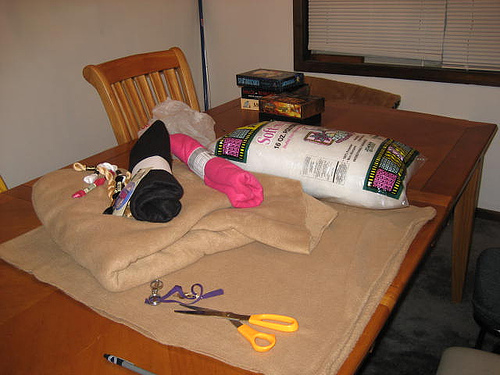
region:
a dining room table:
[7, 22, 494, 350]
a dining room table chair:
[65, 20, 257, 167]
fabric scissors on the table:
[122, 260, 276, 362]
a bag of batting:
[201, 77, 474, 241]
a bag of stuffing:
[215, 99, 492, 262]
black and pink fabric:
[102, 102, 307, 249]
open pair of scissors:
[152, 265, 287, 372]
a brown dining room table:
[314, 66, 496, 221]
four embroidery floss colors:
[32, 134, 176, 223]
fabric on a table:
[58, 72, 460, 371]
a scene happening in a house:
[5, 3, 483, 373]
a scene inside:
[12, 10, 492, 342]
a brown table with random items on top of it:
[23, 51, 498, 373]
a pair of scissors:
[164, 288, 314, 357]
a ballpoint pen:
[92, 340, 167, 374]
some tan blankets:
[12, 155, 396, 372]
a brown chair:
[77, 37, 206, 154]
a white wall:
[0, 0, 229, 191]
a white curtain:
[293, 2, 498, 74]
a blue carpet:
[327, 190, 495, 367]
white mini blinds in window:
[301, 9, 499, 76]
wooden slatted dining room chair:
[79, 54, 219, 151]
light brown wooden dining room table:
[8, 295, 80, 372]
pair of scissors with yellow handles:
[173, 301, 305, 358]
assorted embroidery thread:
[61, 144, 130, 212]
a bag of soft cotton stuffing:
[216, 114, 435, 212]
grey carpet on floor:
[390, 296, 434, 373]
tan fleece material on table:
[254, 258, 396, 301]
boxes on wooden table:
[224, 65, 345, 126]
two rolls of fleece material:
[128, 119, 270, 237]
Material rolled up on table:
[120, 122, 291, 240]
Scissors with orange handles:
[178, 301, 335, 372]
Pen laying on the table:
[94, 350, 154, 374]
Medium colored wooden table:
[29, 305, 65, 360]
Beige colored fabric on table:
[246, 261, 400, 357]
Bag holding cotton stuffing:
[222, 117, 434, 205]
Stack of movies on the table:
[230, 57, 331, 133]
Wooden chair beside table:
[73, 55, 222, 125]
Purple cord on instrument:
[140, 272, 268, 302]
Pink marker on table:
[71, 174, 113, 209]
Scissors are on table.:
[0, 64, 494, 374]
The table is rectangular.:
[1, 70, 498, 373]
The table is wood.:
[0, 68, 499, 373]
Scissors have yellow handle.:
[172, 293, 302, 361]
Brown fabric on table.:
[1, 58, 495, 373]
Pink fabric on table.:
[4, 67, 488, 372]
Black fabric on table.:
[6, 55, 496, 370]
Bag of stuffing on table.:
[3, 54, 499, 359]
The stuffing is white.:
[186, 102, 451, 237]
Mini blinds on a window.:
[285, 0, 499, 92]